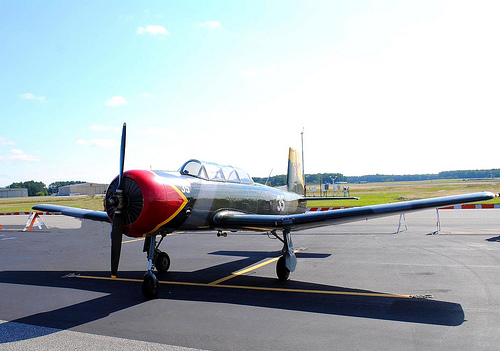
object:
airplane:
[32, 122, 499, 298]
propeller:
[110, 122, 126, 282]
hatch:
[179, 159, 255, 185]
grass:
[466, 183, 499, 204]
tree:
[8, 181, 82, 197]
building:
[57, 182, 109, 196]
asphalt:
[0, 208, 500, 350]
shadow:
[0, 250, 464, 344]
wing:
[212, 191, 497, 235]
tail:
[285, 147, 360, 201]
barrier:
[22, 211, 49, 232]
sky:
[0, 0, 499, 184]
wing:
[30, 204, 111, 224]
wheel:
[274, 256, 291, 282]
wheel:
[140, 275, 158, 298]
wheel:
[153, 251, 173, 273]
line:
[71, 273, 413, 299]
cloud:
[24, 93, 47, 103]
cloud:
[135, 22, 170, 36]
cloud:
[105, 93, 130, 106]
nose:
[105, 168, 185, 239]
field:
[297, 179, 498, 212]